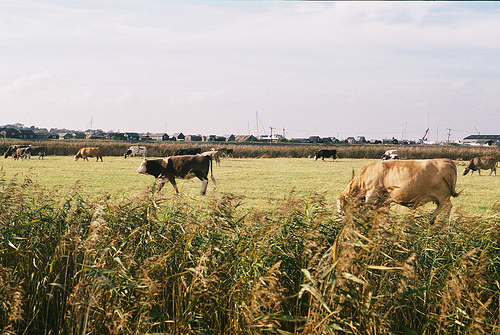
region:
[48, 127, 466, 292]
cattles are in the field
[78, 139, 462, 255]
cattles are grazing at a distance from each other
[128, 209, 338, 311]
the plants are tall in height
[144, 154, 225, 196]
the cow is black and white in color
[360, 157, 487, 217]
the cow is brown in color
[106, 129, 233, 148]
hopuses apear far awy from the view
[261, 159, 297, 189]
grasses are green in color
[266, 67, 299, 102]
sky is coverd of white clouds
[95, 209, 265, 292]
plants are green in coplor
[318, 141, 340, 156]
cow is black in color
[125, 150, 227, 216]
This is a cow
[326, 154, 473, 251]
This is a cow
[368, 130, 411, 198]
This is a cow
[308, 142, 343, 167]
This is a cow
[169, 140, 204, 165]
This is a cow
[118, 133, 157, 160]
This is a cow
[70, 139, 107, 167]
This is a cow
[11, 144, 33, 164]
This is a cow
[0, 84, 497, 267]
cattle grazing in a field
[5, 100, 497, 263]
cows grazing in a field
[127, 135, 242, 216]
a holstein cow in a field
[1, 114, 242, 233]
several cows in a field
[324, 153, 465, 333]
a cow grazing behind grass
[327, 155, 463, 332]
a tan cow that is grazing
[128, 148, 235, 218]
a cow going for a walk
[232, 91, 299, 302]
sky, utility poles with a pasture in the foreground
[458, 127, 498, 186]
a distant cow grazing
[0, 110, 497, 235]
a field of cattle grazing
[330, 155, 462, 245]
Section of a cow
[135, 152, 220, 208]
Section of a cow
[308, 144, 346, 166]
Section of a cow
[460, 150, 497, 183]
Section of a cow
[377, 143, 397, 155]
Section of a cow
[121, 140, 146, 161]
Section of a cow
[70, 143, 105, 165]
Section of a cow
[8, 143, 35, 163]
Section of a cow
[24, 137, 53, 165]
Section of a cow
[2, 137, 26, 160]
Section of a cow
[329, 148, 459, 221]
cow standing in field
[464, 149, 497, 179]
cow standing in field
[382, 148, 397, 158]
cow standing in field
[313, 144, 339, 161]
cow standing in field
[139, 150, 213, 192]
cow standing in field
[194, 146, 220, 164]
cow standing in field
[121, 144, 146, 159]
cow standing in field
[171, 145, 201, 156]
cow standing in field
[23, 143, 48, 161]
cow standing in field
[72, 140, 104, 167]
cow standing in field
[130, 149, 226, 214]
cow in the grass is black and white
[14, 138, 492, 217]
Cows in a field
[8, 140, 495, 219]
Group of cows in a field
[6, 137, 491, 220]
Cows in the grass